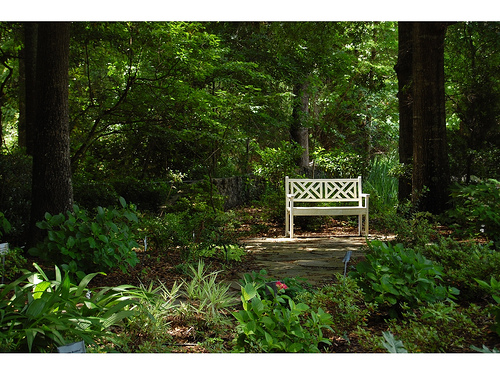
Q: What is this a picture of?
A: A bench in a forest.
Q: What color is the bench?
A: White.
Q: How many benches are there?
A: One.